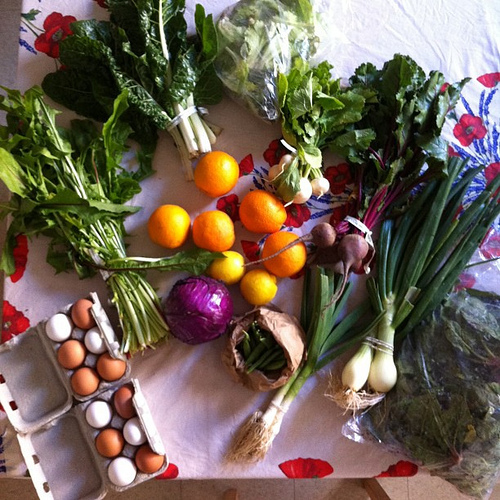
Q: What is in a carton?
A: Eggs.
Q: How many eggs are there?
A: 12.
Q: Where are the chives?
A: Right side.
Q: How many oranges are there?
A: 5.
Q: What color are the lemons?
A: Yellow.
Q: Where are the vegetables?
A: Table.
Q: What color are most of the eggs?
A: Brown.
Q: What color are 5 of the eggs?
A: White.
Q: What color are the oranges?
A: Orange.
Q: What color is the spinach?
A: Green.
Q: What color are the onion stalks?
A: Green.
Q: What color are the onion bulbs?
A: White.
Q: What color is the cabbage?
A: Purple.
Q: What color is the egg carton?
A: Brown.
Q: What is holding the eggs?
A: A carton.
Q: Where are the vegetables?
A: On a table.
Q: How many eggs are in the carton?
A: 12.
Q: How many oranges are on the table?
A: Five.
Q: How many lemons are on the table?
A: Two.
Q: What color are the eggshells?
A: Brown and white.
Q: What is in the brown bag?
A: Pea pods.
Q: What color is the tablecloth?
A: White with red flowers.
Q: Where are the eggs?
A: In a carton.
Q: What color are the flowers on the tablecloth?
A: Red.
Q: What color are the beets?
A: Purple.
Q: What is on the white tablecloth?
A: Red flowers.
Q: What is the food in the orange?
A: Orange.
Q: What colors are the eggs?
A: White and brown.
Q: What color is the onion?
A: Red.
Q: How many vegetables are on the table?
A: Eight.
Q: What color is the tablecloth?
A: White.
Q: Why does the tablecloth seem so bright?
A: The light is shining.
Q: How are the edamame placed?
A: They are placed in a bag.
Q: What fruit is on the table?
A: Oranges.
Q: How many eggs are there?
A: 12.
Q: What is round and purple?
A: Onions.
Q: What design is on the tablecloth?
A: Flowers.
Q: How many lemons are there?
A: 2.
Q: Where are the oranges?
A: In the middle.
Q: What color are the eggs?
A: Brown and white.